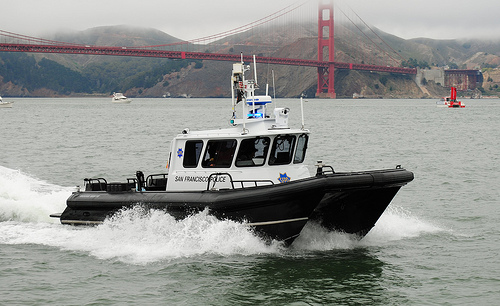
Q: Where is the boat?
A: In the water.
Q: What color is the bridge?
A: Red.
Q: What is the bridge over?
A: Water.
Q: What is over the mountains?
A: Fog.